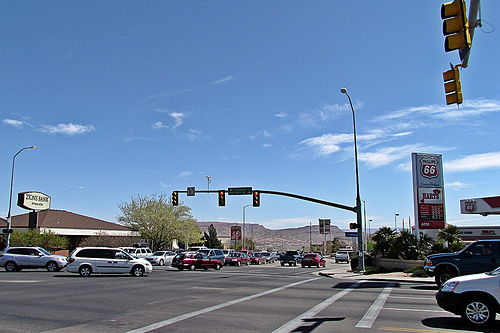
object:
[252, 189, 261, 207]
lights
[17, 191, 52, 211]
sign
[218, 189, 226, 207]
lights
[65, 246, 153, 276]
van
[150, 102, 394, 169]
clouds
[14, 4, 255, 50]
sky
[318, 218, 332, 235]
sign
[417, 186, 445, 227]
prices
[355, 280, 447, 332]
crosswalk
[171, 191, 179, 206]
light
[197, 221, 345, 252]
mountains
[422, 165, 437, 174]
number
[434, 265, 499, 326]
cars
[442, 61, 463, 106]
light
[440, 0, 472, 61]
light